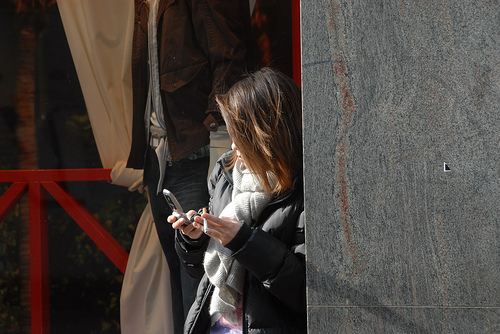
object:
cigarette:
[202, 206, 209, 234]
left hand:
[188, 211, 242, 246]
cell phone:
[161, 188, 193, 224]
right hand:
[164, 210, 203, 241]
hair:
[214, 67, 301, 198]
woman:
[162, 66, 307, 333]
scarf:
[201, 158, 280, 329]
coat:
[175, 151, 307, 333]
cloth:
[56, 0, 175, 333]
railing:
[0, 167, 131, 332]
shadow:
[308, 261, 430, 333]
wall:
[301, 0, 500, 333]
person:
[128, 1, 249, 333]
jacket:
[124, 2, 247, 171]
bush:
[57, 192, 151, 332]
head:
[223, 73, 303, 172]